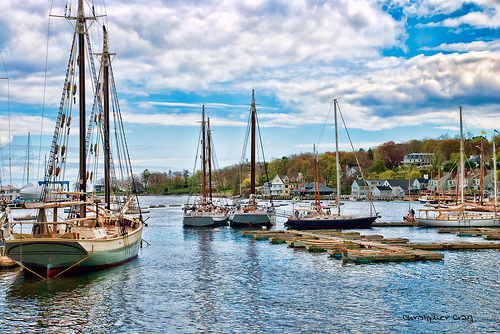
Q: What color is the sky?
A: Blue.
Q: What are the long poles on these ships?
A: Masts.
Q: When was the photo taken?
A: Daytime.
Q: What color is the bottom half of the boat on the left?
A: Green.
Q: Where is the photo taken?
A: Marina.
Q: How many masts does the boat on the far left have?
A: Two.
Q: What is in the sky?
A: Clouds.